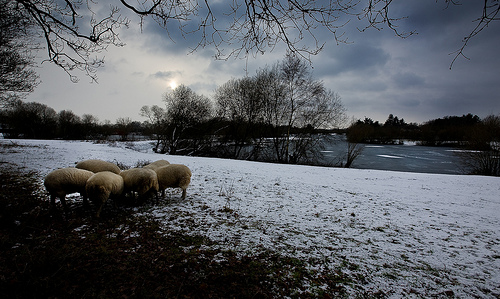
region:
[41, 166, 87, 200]
a white grazing sheep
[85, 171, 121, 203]
a white grazing sheep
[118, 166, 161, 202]
a white grazing sheep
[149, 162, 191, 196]
a white grazing sheep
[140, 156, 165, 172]
a white grazing sheep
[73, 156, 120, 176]
a white grazing sheep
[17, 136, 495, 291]
lightly snow covered ground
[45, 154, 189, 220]
a group of sheep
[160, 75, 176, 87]
cloud covered overcast sun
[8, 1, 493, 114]
a cloudy grey sky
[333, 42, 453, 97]
the sky is gray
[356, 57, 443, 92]
the sky is dark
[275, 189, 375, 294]
the snow is thin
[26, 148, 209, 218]
the sheep are all together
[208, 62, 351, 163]
the tree is brown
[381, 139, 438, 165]
the lake is frozen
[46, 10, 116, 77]
the limb is small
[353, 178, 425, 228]
the snow is white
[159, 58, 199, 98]
the sun is shining through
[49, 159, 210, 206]
the sheep are white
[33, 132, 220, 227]
Group of sheep gathered together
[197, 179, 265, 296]
The snow is melting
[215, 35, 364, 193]
All of the trees have lost their leaves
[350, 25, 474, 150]
The sky is cloudy and stormy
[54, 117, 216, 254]
The sheep have been sheared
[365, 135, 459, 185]
Frozen pond beside hill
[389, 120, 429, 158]
small house in background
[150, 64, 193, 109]
Sun is behind the clouds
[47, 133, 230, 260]
The sheep are eating grass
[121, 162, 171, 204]
Sheep has no tail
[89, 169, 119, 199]
sheep grazing on snow covered ground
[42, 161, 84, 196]
sheep grazing on snow covered ground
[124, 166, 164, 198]
sheep grazing on snow covered ground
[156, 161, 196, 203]
sheep grazing on snow covered ground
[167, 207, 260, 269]
ground covered by white snow and brown leaves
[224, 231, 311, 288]
ground covered by white snow and brown leaves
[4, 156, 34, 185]
ground covered by white snow and brown leaves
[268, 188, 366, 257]
ground covered by white snow and brown leaves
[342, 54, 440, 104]
gray and white clouds against blue sky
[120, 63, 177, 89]
gray and white clouds against blue sky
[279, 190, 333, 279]
a snow covered field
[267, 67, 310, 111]
branches of a tree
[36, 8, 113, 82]
branches of a tree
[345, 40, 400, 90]
the clouds in the sky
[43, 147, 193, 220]
a herd of sheep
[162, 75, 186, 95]
the sun in the sky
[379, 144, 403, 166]
frozen over water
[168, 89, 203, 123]
branches of a tree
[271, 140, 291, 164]
the trunks of trees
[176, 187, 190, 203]
a leg of a sheep